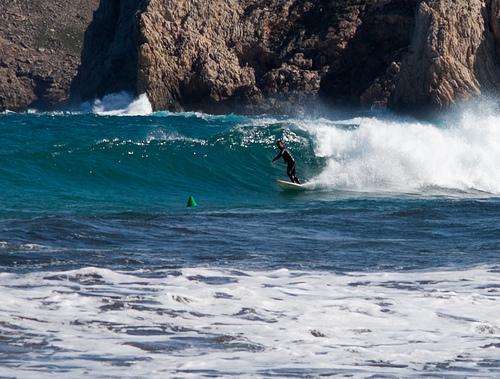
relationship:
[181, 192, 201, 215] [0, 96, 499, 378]
cone in water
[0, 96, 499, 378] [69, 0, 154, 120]
water hitting shadow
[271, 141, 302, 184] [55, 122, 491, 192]
man in wave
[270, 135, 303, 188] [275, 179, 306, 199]
man on surfboard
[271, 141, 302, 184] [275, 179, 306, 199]
man on surfboard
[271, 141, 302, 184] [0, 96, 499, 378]
man in water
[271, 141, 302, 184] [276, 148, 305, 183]
man wearing wetsuit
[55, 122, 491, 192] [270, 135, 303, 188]
wave behind man